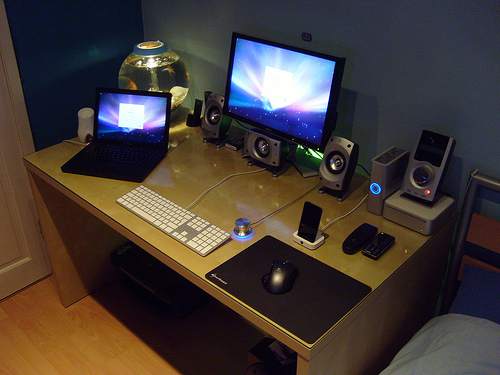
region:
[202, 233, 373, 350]
black mouse on black mouse pad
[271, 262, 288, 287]
light glare on mouse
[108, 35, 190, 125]
fish bowl in desk corner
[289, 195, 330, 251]
iPod charging in dock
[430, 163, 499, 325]
wooden chair with silver frame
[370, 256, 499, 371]
blue cushions on wooden chair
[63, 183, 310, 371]
dark shadow under desk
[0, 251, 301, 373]
light brown hardwood floor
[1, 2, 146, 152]
dark blue wall next to white door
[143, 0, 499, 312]
light blue wall behind desk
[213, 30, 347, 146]
computer display on table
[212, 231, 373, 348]
mouse pad on table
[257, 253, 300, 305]
a mouse on mouse pad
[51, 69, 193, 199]
laptop on a table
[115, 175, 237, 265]
keyboard on a table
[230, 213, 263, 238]
a control set on a table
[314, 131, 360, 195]
speaker on a table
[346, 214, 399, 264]
cellphone on a table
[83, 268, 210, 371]
shadow under a table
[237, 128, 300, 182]
computer speaker on a table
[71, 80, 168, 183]
the laptop on the desk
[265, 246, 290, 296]
the mouse on the mouse pad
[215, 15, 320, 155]
the monitor is on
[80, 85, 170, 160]
the laptop is on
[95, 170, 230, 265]
the keyboard on the desk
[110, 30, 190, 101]
the fishbowl on the desk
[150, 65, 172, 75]
fish in the fish bowl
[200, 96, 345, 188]
speakers beside the monitor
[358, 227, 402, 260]
the cellphone on the desk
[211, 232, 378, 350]
the mouse pad is black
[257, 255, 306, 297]
the mouse is black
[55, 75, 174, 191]
laptop screen is on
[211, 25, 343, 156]
the computer screen is on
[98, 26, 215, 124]
fish in a bowl next to laptop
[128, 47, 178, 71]
light in the bowl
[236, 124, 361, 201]
speakers near the screen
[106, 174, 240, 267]
keyboard is white and gray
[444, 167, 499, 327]
brown chair next to desk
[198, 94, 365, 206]
the speakers are gray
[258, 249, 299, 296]
computer mouse sitting on desk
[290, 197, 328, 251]
cell phone sitting on charger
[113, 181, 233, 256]
white computer keyboard sitting on desk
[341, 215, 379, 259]
black remote control sitting on desk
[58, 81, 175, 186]
black laptop computer sitting on desk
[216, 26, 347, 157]
computer screen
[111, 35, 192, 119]
fish bowl sitting on desk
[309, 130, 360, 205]
speaker sitting on desk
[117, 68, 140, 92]
goldfish inside of fish bowl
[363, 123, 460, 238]
equipment sitting on desk